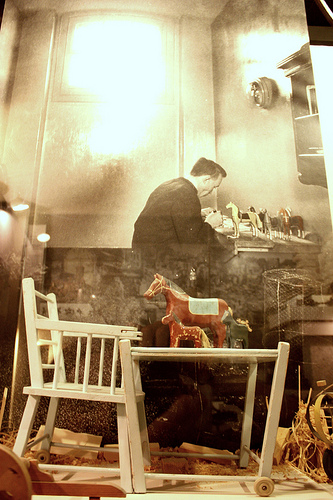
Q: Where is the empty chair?
A: Next to desk.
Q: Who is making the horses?
A: The man.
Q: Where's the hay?
A: On ground.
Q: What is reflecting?
A: Light.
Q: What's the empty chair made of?
A: Wood.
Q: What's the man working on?
A: Horses.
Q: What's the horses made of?
A: Wood.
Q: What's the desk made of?
A: Wood.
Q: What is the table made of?
A: Wood.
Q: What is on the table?
A: Toys.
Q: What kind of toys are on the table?
A: Horses.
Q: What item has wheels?
A: The table.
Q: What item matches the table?
A: The chair.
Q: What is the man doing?
A: Making toys.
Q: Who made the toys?
A: The man in the coat.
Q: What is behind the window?
A: A toy display.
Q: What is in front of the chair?
A: A table.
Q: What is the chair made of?
A: Wood.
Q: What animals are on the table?
A: Horses.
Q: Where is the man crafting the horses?
A: Wood shop.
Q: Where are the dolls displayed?
A: Museum.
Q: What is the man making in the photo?
A: Toy horses.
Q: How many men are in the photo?
A: One.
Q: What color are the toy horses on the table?
A: Brown.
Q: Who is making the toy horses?
A: The man.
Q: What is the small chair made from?
A: Wood.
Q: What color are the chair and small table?
A: Tan.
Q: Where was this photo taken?
A: In a workshop.